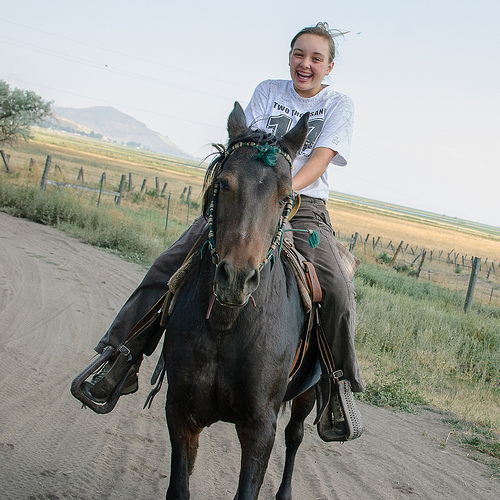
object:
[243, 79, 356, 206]
shirt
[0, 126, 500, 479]
grass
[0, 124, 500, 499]
ground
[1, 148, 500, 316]
fence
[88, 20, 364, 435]
girl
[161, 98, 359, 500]
horse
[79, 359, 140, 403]
shoe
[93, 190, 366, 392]
pants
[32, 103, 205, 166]
mountain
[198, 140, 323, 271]
bridle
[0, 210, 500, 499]
dirt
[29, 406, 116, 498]
tracks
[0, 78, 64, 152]
tree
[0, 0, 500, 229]
sky